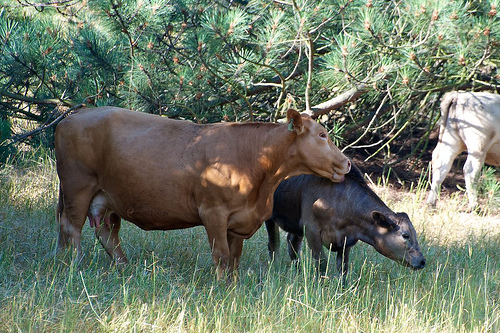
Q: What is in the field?
A: The cow.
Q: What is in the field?
A: The cow.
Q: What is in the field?
A: The cow.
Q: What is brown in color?
A: The large cow.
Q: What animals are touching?
A: Cows.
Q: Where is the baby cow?
A: Under the mother.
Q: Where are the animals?
A: The field.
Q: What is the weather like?
A: Sunny.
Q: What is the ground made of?
A: Grass.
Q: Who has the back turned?
A: White cow.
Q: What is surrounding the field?
A: Trees.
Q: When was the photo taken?
A: Morning.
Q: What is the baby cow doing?
A: Looking down.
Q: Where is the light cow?
A: The corner.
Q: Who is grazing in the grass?
A: Cows.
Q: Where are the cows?
A: Grazing in the grass.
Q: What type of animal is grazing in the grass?
A: Cows.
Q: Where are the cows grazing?
A: In the grass.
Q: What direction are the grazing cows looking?
A: To the right.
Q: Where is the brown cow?
A: In the grass.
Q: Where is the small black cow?
A: Next to the brown cow.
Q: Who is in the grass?
A: Cows.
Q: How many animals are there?
A: 3.